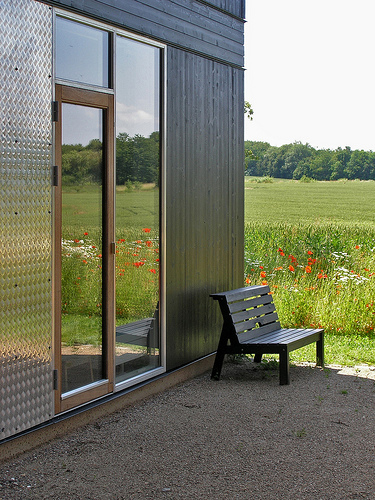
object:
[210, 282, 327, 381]
bench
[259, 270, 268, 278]
flowers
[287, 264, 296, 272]
flower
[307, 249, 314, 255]
flower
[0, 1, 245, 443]
building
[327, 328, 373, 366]
grass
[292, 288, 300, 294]
flower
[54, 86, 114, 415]
door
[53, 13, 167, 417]
mirror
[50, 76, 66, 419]
siding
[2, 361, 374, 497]
patio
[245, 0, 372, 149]
sky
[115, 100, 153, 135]
cloud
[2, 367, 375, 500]
gravel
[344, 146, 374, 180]
trees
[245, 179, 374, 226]
grass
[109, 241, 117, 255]
handle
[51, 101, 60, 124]
hinge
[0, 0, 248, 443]
home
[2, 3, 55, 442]
metal surface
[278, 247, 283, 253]
flowers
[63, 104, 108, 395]
glass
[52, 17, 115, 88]
window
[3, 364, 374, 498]
ground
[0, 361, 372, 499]
shade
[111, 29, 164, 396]
glass